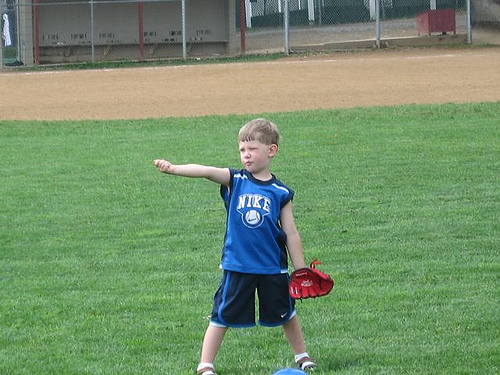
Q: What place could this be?
A: It is a field.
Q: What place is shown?
A: It is a field.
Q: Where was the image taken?
A: It was taken at the field.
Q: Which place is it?
A: It is a field.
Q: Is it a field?
A: Yes, it is a field.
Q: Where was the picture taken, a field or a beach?
A: It was taken at a field.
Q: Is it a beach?
A: No, it is a field.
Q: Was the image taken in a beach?
A: No, the picture was taken in a field.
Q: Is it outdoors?
A: Yes, it is outdoors.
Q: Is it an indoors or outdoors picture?
A: It is outdoors.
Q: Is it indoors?
A: No, it is outdoors.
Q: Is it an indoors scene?
A: No, it is outdoors.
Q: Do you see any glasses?
A: No, there are no glasses.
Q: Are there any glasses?
A: No, there are no glasses.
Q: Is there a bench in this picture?
A: Yes, there is a bench.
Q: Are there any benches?
A: Yes, there is a bench.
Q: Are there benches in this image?
A: Yes, there is a bench.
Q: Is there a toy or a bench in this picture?
A: Yes, there is a bench.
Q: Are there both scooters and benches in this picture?
A: No, there is a bench but no scooters.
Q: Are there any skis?
A: No, there are no skis.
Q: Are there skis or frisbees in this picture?
A: No, there are no skis or frisbees.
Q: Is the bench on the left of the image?
A: Yes, the bench is on the left of the image.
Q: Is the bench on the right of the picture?
A: No, the bench is on the left of the image.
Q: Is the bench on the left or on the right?
A: The bench is on the left of the image.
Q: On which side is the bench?
A: The bench is on the left of the image.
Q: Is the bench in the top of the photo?
A: Yes, the bench is in the top of the image.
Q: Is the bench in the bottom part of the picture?
A: No, the bench is in the top of the image.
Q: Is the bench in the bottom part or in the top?
A: The bench is in the top of the image.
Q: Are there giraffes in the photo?
A: No, there are no giraffes.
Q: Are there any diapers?
A: No, there are no diapers.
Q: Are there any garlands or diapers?
A: No, there are no diapers or garlands.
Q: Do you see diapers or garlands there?
A: No, there are no diapers or garlands.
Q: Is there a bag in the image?
A: No, there are no bags.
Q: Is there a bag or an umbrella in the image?
A: No, there are no bags or umbrellas.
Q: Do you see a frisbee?
A: No, there are no frisbees.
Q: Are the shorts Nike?
A: Yes, the shorts are nike.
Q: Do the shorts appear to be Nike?
A: Yes, the shorts are nike.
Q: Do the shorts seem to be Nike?
A: Yes, the shorts are nike.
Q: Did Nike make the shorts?
A: Yes, the shorts were made by nike.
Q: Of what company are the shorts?
A: The shorts are nike.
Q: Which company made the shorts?
A: Nike made nike.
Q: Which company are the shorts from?
A: The shorts are from nike.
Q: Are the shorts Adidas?
A: No, the shorts are nike.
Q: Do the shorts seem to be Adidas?
A: No, the shorts are nike.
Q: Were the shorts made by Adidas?
A: No, the shorts were made by nike.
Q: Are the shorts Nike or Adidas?
A: The shorts are nike.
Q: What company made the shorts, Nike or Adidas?
A: The shorts were made nike.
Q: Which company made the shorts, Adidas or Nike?
A: The shorts were made nike.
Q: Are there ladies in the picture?
A: No, there are no ladies.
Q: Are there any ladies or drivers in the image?
A: No, there are no ladies or drivers.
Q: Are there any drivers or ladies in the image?
A: No, there are no ladies or drivers.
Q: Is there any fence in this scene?
A: Yes, there is a fence.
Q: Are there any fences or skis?
A: Yes, there is a fence.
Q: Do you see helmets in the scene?
A: No, there are no helmets.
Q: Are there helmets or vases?
A: No, there are no helmets or vases.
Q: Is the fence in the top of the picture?
A: Yes, the fence is in the top of the image.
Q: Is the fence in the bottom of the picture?
A: No, the fence is in the top of the image.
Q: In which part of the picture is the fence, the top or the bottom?
A: The fence is in the top of the image.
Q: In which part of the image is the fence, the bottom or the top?
A: The fence is in the top of the image.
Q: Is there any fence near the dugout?
A: Yes, there is a fence near the dugout.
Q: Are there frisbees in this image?
A: No, there are no frisbees.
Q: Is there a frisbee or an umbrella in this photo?
A: No, there are no frisbees or umbrellas.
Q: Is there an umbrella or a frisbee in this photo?
A: No, there are no frisbees or umbrellas.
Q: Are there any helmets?
A: No, there are no helmets.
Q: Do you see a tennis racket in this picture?
A: No, there are no rackets.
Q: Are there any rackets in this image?
A: No, there are no rackets.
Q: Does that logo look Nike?
A: Yes, the logo is nike.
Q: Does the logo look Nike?
A: Yes, the logo is nike.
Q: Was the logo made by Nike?
A: Yes, the logo was made by nike.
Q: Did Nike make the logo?
A: Yes, the logo was made by nike.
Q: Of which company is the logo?
A: The logo is nike.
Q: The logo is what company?
A: The logo is nike.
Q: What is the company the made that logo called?
A: The company is nike.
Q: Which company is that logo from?
A: The logo is from nike.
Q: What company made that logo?
A: Nike made nike.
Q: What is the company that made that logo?
A: The company that made the logo is nike.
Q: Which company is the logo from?
A: The logo is from nike.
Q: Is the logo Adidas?
A: No, the logo is nike.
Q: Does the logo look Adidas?
A: No, the logo is nike.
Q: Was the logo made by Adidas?
A: No, the logo was made by nike.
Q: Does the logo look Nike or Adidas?
A: The logo is nike.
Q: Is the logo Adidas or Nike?
A: The logo is nike.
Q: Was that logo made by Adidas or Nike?
A: The logo was made nike.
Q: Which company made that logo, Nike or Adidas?
A: The logo was made nike.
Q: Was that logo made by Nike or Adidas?
A: The logo was made nike.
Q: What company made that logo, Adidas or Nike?
A: The logo was made nike.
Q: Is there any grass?
A: Yes, there is grass.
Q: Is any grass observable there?
A: Yes, there is grass.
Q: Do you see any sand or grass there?
A: Yes, there is grass.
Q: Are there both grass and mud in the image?
A: No, there is grass but no mud.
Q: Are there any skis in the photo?
A: No, there are no skis.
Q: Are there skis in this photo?
A: No, there are no skis.